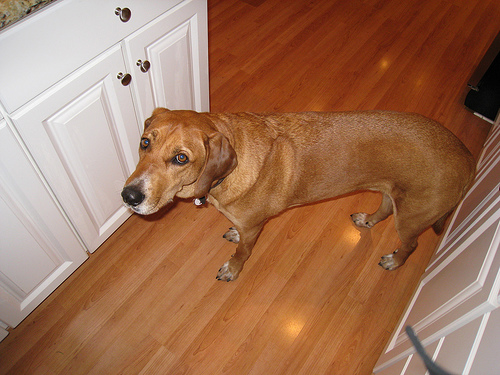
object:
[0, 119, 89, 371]
cabinets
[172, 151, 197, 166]
eyes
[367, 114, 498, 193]
cabinet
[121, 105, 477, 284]
dog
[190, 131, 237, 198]
ear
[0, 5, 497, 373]
kitchen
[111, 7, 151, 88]
knobs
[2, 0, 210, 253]
cabinet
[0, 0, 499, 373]
board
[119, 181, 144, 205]
nose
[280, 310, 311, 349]
light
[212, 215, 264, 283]
leg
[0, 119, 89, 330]
panels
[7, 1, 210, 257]
cabinet doors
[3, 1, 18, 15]
countertop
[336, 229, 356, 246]
light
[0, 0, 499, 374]
floor